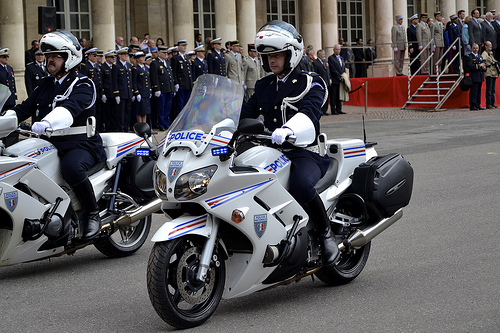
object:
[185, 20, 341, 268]
policeman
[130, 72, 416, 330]
motorcycle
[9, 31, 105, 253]
policeman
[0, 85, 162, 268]
motorcycle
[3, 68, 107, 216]
uniform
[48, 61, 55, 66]
mustache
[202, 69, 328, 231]
uniform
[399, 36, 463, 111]
stairs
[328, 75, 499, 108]
platform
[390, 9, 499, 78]
people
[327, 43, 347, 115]
man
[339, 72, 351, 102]
overcoat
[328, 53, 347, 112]
suit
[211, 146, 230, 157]
light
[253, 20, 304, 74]
helmet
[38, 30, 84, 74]
helmet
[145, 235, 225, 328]
tire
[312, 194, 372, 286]
tire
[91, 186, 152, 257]
tire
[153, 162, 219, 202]
headlights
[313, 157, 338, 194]
seat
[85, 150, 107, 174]
seat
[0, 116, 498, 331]
street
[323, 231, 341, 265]
foot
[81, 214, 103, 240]
foot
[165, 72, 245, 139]
windshield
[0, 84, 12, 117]
windshield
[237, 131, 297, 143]
handle bar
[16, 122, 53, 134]
handle bar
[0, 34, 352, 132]
officers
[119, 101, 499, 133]
sidewalk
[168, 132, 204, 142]
word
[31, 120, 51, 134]
glove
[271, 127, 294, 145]
glove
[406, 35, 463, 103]
railing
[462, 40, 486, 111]
men